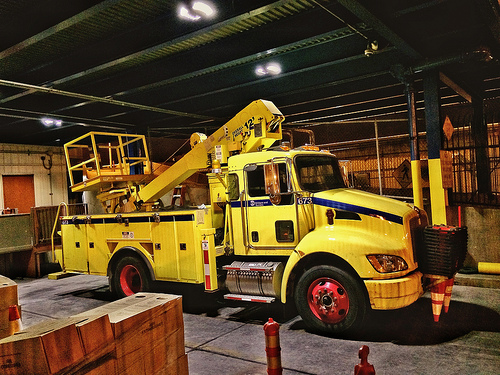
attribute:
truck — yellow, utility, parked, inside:
[52, 142, 407, 313]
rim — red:
[314, 287, 347, 321]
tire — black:
[281, 263, 362, 339]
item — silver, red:
[223, 266, 282, 303]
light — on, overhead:
[177, 1, 223, 21]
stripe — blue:
[64, 215, 206, 227]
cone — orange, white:
[418, 276, 454, 331]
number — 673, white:
[299, 200, 318, 207]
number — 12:
[243, 116, 254, 130]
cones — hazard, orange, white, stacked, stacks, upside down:
[427, 278, 454, 313]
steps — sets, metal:
[210, 253, 285, 311]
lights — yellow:
[280, 139, 338, 156]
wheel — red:
[306, 277, 350, 324]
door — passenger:
[238, 163, 294, 246]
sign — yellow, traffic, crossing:
[437, 103, 464, 140]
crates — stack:
[10, 297, 188, 374]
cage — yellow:
[58, 128, 149, 187]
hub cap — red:
[115, 262, 142, 295]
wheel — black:
[112, 254, 146, 306]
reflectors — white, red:
[199, 246, 222, 296]